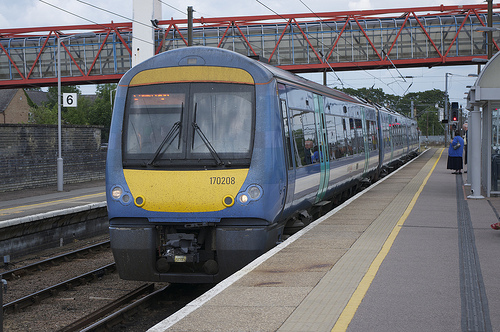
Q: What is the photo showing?
A: It is showing a train station.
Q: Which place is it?
A: It is a train station.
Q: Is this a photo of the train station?
A: Yes, it is showing the train station.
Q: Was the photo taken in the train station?
A: Yes, it was taken in the train station.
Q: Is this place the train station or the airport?
A: It is the train station.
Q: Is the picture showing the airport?
A: No, the picture is showing the train station.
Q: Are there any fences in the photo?
A: No, there are no fences.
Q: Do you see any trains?
A: Yes, there is a train.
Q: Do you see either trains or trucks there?
A: Yes, there is a train.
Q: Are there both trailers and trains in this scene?
A: No, there is a train but no trailers.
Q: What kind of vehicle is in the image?
A: The vehicle is a train.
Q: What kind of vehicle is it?
A: The vehicle is a train.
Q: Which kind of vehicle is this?
A: That is a train.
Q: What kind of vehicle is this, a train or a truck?
A: That is a train.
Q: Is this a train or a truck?
A: This is a train.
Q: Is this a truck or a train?
A: This is a train.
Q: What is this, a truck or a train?
A: This is a train.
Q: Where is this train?
A: The train is at the train station.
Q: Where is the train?
A: The train is at the train station.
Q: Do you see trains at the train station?
A: Yes, there is a train at the train station.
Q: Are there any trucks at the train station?
A: No, there is a train at the train station.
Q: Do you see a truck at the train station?
A: No, there is a train at the train station.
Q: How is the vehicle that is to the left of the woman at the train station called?
A: The vehicle is a train.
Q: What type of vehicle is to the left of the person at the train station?
A: The vehicle is a train.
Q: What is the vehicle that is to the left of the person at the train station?
A: The vehicle is a train.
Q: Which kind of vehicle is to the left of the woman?
A: The vehicle is a train.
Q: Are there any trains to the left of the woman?
A: Yes, there is a train to the left of the woman.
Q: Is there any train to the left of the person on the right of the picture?
A: Yes, there is a train to the left of the woman.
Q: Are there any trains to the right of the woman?
A: No, the train is to the left of the woman.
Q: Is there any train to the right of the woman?
A: No, the train is to the left of the woman.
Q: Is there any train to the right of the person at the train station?
A: No, the train is to the left of the woman.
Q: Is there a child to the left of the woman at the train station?
A: No, there is a train to the left of the woman.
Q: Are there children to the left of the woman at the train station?
A: No, there is a train to the left of the woman.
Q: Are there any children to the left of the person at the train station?
A: No, there is a train to the left of the woman.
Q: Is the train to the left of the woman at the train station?
A: Yes, the train is to the left of the woman.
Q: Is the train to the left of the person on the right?
A: Yes, the train is to the left of the woman.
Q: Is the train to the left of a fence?
A: No, the train is to the left of the woman.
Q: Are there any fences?
A: No, there are no fences.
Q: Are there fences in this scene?
A: No, there are no fences.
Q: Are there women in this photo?
A: Yes, there is a woman.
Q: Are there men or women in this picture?
A: Yes, there is a woman.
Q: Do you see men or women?
A: Yes, there is a woman.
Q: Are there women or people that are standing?
A: Yes, the woman is standing.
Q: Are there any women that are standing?
A: Yes, there is a woman that is standing.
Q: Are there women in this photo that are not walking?
A: Yes, there is a woman that is standing.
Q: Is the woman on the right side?
A: Yes, the woman is on the right of the image.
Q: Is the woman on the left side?
A: No, the woman is on the right of the image.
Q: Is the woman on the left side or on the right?
A: The woman is on the right of the image.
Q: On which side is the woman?
A: The woman is on the right of the image.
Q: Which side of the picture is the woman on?
A: The woman is on the right of the image.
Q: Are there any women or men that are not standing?
A: No, there is a woman but she is standing.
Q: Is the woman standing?
A: Yes, the woman is standing.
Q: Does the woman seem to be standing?
A: Yes, the woman is standing.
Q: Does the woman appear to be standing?
A: Yes, the woman is standing.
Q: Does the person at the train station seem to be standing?
A: Yes, the woman is standing.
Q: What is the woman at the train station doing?
A: The woman is standing.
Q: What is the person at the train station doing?
A: The woman is standing.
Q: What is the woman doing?
A: The woman is standing.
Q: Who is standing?
A: The woman is standing.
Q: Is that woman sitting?
A: No, the woman is standing.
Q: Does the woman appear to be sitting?
A: No, the woman is standing.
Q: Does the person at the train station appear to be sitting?
A: No, the woman is standing.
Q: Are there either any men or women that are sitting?
A: No, there is a woman but she is standing.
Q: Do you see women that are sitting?
A: No, there is a woman but she is standing.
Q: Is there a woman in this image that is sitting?
A: No, there is a woman but she is standing.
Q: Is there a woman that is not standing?
A: No, there is a woman but she is standing.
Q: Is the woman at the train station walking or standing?
A: The woman is standing.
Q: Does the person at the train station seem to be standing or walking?
A: The woman is standing.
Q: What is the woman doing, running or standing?
A: The woman is standing.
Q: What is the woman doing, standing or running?
A: The woman is standing.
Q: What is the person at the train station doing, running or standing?
A: The woman is standing.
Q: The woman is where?
A: The woman is at the train station.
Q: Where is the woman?
A: The woman is at the train station.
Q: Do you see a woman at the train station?
A: Yes, there is a woman at the train station.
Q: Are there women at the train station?
A: Yes, there is a woman at the train station.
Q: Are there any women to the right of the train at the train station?
A: Yes, there is a woman to the right of the train.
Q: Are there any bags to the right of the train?
A: No, there is a woman to the right of the train.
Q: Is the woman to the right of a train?
A: Yes, the woman is to the right of a train.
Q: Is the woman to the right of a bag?
A: No, the woman is to the right of a train.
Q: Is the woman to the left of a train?
A: No, the woman is to the right of a train.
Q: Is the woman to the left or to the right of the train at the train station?
A: The woman is to the right of the train.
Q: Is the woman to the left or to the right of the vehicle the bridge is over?
A: The woman is to the right of the train.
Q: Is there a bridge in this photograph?
A: Yes, there is a bridge.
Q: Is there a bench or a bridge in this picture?
A: Yes, there is a bridge.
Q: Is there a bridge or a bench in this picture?
A: Yes, there is a bridge.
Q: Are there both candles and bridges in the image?
A: No, there is a bridge but no candles.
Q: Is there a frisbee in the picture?
A: No, there are no frisbees.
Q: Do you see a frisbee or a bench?
A: No, there are no frisbees or benches.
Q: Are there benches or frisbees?
A: No, there are no frisbees or benches.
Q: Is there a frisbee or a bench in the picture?
A: No, there are no frisbees or benches.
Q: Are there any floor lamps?
A: No, there are no floor lamps.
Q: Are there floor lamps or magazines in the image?
A: No, there are no floor lamps or magazines.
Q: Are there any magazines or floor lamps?
A: No, there are no floor lamps or magazines.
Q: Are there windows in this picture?
A: Yes, there are windows.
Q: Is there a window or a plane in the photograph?
A: Yes, there are windows.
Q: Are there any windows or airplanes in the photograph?
A: Yes, there are windows.